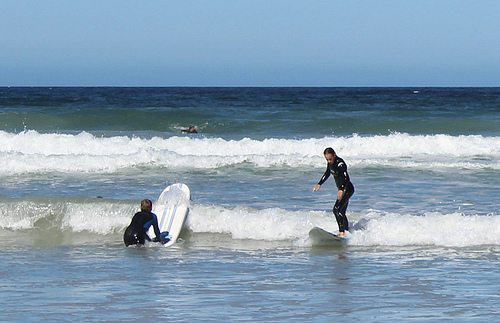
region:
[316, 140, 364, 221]
this is a man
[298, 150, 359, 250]
the man is sea surfing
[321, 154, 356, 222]
the man is wet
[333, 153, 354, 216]
the costumes are black in color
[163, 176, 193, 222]
this is a surf board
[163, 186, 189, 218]
the surf board is white in color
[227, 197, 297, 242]
this is a wave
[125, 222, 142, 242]
these are the butt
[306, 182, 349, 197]
the hands are in front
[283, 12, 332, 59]
the sky is bue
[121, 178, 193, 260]
The surfer that is getting on their board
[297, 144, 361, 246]
The surfer riding their board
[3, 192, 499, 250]
The wave currently being ridden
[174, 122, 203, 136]
The surfer about to ride a wave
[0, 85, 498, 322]
The ocean the surfers are in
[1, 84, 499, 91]
The horizon line made by the ocean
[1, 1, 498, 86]
The sky above the horizon line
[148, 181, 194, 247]
The surfboard facing out into the ocean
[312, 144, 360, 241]
The surfer standing on the surfboard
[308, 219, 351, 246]
The surfboard with the standing surfer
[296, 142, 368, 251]
SUrfer in the sea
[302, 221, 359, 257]
Surfboard is white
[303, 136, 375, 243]
Surfer has balck wetsuit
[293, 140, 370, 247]
Surfer has hands in front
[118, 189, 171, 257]
Surfer pulling a surfboard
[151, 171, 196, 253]
Surfboard is white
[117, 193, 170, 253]
Wetsuit is black and blue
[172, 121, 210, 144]
Surfer on a wave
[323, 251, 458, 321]
Reflection of person on water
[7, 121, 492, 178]
Wave roll in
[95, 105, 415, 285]
three surfers in the ocean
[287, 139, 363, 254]
the surfer's wetsuit is black and shiny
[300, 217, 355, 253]
the surfboard is white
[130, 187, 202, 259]
the other surfboard is white with blue stripes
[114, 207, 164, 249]
the surfer's wetsuit is black and blue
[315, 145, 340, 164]
the surfer has dark hair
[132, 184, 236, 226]
the waves are crashing onto the surfboard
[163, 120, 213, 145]
the surfer in the distance is paddling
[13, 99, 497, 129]
another wave is coming from the distance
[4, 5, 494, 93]
the sky is blue and cloudless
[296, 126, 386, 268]
man standing on board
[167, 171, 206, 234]
white board under man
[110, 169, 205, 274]
man heading into the water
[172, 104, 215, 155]
person far out in water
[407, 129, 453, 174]
white water next to surfers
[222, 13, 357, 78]
blue sky above the ocean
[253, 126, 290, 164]
wave coming into the beach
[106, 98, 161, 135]
water about to turn into a wave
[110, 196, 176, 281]
man wearing a wetsuit